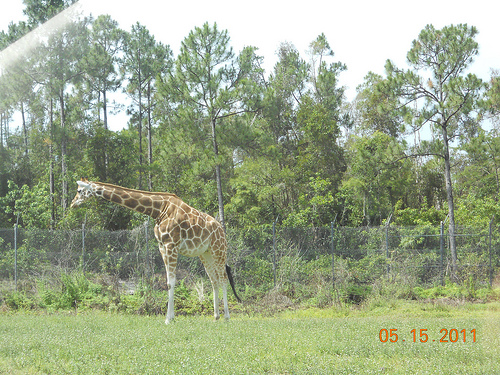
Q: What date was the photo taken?
A: May 15, 2011.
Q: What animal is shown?
A: Giraffe.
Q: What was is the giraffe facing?
A: Left.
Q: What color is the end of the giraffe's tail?
A: Black.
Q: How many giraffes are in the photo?
A: 1.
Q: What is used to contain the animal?
A: A fence.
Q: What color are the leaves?
A: Green.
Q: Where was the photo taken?
A: Safari park.